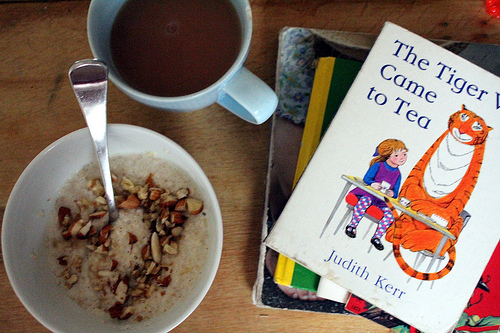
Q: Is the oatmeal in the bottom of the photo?
A: Yes, the oatmeal is in the bottom of the image.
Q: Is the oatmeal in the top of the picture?
A: No, the oatmeal is in the bottom of the image.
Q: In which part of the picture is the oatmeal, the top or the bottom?
A: The oatmeal is in the bottom of the image.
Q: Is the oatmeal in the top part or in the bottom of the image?
A: The oatmeal is in the bottom of the image.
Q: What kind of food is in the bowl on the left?
A: The food is oatmeal.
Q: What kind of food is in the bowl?
A: The food is oatmeal.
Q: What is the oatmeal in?
A: The oatmeal is in the bowl.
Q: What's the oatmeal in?
A: The oatmeal is in the bowl.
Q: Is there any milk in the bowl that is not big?
A: No, there is oatmeal in the bowl.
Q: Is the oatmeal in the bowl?
A: Yes, the oatmeal is in the bowl.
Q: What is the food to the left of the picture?
A: The food is oatmeal.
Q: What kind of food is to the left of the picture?
A: The food is oatmeal.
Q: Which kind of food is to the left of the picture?
A: The food is oatmeal.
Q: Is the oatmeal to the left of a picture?
A: Yes, the oatmeal is to the left of a picture.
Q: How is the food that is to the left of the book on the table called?
A: The food is oatmeal.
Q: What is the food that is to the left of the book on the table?
A: The food is oatmeal.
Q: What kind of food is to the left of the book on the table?
A: The food is oatmeal.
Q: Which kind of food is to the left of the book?
A: The food is oatmeal.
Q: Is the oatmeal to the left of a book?
A: Yes, the oatmeal is to the left of a book.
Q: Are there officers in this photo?
A: No, there are no officers.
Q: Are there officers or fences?
A: No, there are no officers or fences.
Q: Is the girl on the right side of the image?
A: Yes, the girl is on the right of the image.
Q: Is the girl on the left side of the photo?
A: No, the girl is on the right of the image.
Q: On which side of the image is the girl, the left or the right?
A: The girl is on the right of the image.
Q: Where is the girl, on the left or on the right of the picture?
A: The girl is on the right of the image.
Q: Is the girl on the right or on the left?
A: The girl is on the right of the image.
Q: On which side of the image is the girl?
A: The girl is on the right of the image.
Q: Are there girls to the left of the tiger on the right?
A: Yes, there is a girl to the left of the tiger.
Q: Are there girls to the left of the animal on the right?
A: Yes, there is a girl to the left of the tiger.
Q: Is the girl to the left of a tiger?
A: Yes, the girl is to the left of a tiger.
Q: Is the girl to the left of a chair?
A: No, the girl is to the left of a tiger.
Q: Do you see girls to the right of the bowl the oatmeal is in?
A: Yes, there is a girl to the right of the bowl.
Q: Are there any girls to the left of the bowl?
A: No, the girl is to the right of the bowl.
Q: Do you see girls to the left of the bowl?
A: No, the girl is to the right of the bowl.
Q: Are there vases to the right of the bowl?
A: No, there is a girl to the right of the bowl.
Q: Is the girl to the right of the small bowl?
A: Yes, the girl is to the right of the bowl.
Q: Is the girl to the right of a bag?
A: No, the girl is to the right of the bowl.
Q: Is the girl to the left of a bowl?
A: No, the girl is to the right of a bowl.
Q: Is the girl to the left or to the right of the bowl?
A: The girl is to the right of the bowl.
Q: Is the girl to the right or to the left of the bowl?
A: The girl is to the right of the bowl.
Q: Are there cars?
A: No, there are no cars.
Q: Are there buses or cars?
A: No, there are no cars or buses.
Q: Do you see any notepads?
A: No, there are no notepads.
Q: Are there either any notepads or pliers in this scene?
A: No, there are no notepads or pliers.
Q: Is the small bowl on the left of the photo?
A: Yes, the bowl is on the left of the image.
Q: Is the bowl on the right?
A: No, the bowl is on the left of the image.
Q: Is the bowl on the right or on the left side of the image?
A: The bowl is on the left of the image.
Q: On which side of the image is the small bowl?
A: The bowl is on the left of the image.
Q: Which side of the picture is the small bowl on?
A: The bowl is on the left of the image.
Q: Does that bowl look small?
A: Yes, the bowl is small.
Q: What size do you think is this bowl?
A: The bowl is small.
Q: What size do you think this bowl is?
A: The bowl is small.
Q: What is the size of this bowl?
A: The bowl is small.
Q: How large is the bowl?
A: The bowl is small.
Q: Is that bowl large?
A: No, the bowl is small.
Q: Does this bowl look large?
A: No, the bowl is small.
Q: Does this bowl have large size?
A: No, the bowl is small.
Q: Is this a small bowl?
A: Yes, this is a small bowl.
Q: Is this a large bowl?
A: No, this is a small bowl.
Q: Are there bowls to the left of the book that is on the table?
A: Yes, there is a bowl to the left of the book.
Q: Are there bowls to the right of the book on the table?
A: No, the bowl is to the left of the book.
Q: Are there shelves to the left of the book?
A: No, there is a bowl to the left of the book.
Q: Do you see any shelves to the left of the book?
A: No, there is a bowl to the left of the book.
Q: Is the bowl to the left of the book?
A: Yes, the bowl is to the left of the book.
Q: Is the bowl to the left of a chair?
A: No, the bowl is to the left of the book.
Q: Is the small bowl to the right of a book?
A: No, the bowl is to the left of a book.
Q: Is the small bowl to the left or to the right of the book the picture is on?
A: The bowl is to the left of the book.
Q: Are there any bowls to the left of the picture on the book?
A: Yes, there is a bowl to the left of the picture.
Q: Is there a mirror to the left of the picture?
A: No, there is a bowl to the left of the picture.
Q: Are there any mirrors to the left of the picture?
A: No, there is a bowl to the left of the picture.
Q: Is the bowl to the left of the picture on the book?
A: Yes, the bowl is to the left of the picture.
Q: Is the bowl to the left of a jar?
A: No, the bowl is to the left of the picture.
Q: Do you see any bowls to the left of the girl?
A: Yes, there is a bowl to the left of the girl.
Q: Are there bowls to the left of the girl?
A: Yes, there is a bowl to the left of the girl.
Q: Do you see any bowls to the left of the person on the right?
A: Yes, there is a bowl to the left of the girl.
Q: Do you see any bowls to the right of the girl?
A: No, the bowl is to the left of the girl.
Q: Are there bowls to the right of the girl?
A: No, the bowl is to the left of the girl.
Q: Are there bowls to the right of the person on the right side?
A: No, the bowl is to the left of the girl.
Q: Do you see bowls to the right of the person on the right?
A: No, the bowl is to the left of the girl.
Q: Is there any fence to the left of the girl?
A: No, there is a bowl to the left of the girl.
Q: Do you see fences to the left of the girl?
A: No, there is a bowl to the left of the girl.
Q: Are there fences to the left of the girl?
A: No, there is a bowl to the left of the girl.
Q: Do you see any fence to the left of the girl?
A: No, there is a bowl to the left of the girl.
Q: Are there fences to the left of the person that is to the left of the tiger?
A: No, there is a bowl to the left of the girl.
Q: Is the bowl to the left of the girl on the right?
A: Yes, the bowl is to the left of the girl.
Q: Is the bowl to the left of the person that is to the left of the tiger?
A: Yes, the bowl is to the left of the girl.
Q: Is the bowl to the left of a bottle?
A: No, the bowl is to the left of the girl.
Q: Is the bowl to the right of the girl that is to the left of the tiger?
A: No, the bowl is to the left of the girl.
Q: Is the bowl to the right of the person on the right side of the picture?
A: No, the bowl is to the left of the girl.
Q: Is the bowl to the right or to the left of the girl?
A: The bowl is to the left of the girl.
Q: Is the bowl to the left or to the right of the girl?
A: The bowl is to the left of the girl.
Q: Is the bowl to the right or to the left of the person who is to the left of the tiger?
A: The bowl is to the left of the girl.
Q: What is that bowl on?
A: The bowl is on the table.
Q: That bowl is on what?
A: The bowl is on the table.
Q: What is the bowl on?
A: The bowl is on the table.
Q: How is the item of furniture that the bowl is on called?
A: The piece of furniture is a table.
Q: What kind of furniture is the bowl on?
A: The bowl is on the table.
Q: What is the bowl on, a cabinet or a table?
A: The bowl is on a table.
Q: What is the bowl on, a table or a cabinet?
A: The bowl is on a table.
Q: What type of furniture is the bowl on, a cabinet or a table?
A: The bowl is on a table.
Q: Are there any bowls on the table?
A: Yes, there is a bowl on the table.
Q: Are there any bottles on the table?
A: No, there is a bowl on the table.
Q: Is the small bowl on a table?
A: Yes, the bowl is on a table.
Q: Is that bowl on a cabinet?
A: No, the bowl is on a table.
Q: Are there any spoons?
A: Yes, there is a spoon.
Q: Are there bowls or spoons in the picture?
A: Yes, there is a spoon.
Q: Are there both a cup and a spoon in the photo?
A: Yes, there are both a spoon and a cup.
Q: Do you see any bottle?
A: No, there are no bottles.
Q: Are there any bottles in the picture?
A: No, there are no bottles.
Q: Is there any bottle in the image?
A: No, there are no bottles.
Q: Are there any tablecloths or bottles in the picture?
A: No, there are no bottles or tablecloths.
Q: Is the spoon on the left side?
A: Yes, the spoon is on the left of the image.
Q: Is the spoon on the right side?
A: No, the spoon is on the left of the image.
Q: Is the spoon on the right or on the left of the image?
A: The spoon is on the left of the image.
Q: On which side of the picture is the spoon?
A: The spoon is on the left of the image.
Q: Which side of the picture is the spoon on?
A: The spoon is on the left of the image.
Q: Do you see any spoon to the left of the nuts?
A: Yes, there is a spoon to the left of the nuts.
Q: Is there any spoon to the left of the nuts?
A: Yes, there is a spoon to the left of the nuts.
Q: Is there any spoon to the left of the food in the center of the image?
A: Yes, there is a spoon to the left of the nuts.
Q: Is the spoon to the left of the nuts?
A: Yes, the spoon is to the left of the nuts.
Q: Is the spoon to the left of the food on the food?
A: Yes, the spoon is to the left of the nuts.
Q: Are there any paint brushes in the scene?
A: No, there are no paint brushes.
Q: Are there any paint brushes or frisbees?
A: No, there are no paint brushes or frisbees.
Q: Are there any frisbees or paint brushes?
A: No, there are no paint brushes or frisbees.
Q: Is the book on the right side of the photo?
A: Yes, the book is on the right of the image.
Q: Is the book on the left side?
A: No, the book is on the right of the image.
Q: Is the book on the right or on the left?
A: The book is on the right of the image.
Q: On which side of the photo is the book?
A: The book is on the right of the image.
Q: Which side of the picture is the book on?
A: The book is on the right of the image.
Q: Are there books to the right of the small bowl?
A: Yes, there is a book to the right of the bowl.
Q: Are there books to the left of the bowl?
A: No, the book is to the right of the bowl.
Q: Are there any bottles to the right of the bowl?
A: No, there is a book to the right of the bowl.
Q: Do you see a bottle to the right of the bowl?
A: No, there is a book to the right of the bowl.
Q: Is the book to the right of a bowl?
A: Yes, the book is to the right of a bowl.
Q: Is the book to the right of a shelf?
A: No, the book is to the right of a bowl.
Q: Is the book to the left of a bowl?
A: No, the book is to the right of a bowl.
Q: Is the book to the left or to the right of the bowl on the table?
A: The book is to the right of the bowl.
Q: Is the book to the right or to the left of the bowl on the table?
A: The book is to the right of the bowl.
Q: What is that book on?
A: The book is on the table.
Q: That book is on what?
A: The book is on the table.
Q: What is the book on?
A: The book is on the table.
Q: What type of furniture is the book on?
A: The book is on the table.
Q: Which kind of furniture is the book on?
A: The book is on the table.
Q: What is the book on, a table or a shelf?
A: The book is on a table.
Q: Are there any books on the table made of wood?
A: Yes, there is a book on the table.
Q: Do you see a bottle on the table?
A: No, there is a book on the table.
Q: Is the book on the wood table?
A: Yes, the book is on the table.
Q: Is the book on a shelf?
A: No, the book is on the table.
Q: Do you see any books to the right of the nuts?
A: Yes, there is a book to the right of the nuts.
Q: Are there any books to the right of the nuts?
A: Yes, there is a book to the right of the nuts.